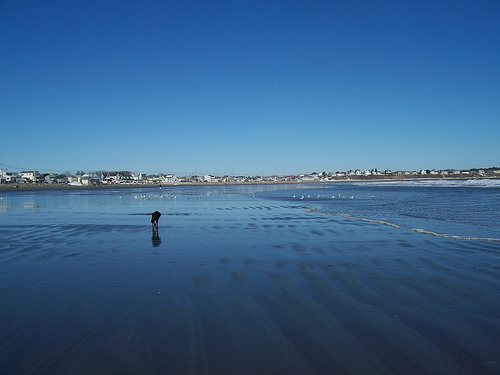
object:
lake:
[0, 186, 470, 362]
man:
[151, 210, 162, 230]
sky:
[79, 40, 474, 142]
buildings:
[165, 173, 175, 184]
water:
[463, 191, 479, 198]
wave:
[426, 184, 441, 189]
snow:
[166, 179, 168, 182]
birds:
[299, 196, 304, 201]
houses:
[336, 171, 341, 177]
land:
[345, 175, 478, 181]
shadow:
[310, 230, 324, 237]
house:
[19, 171, 40, 182]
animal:
[151, 210, 162, 226]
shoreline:
[7, 180, 198, 189]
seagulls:
[331, 195, 335, 198]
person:
[159, 181, 161, 187]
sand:
[165, 184, 170, 186]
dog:
[16, 185, 18, 189]